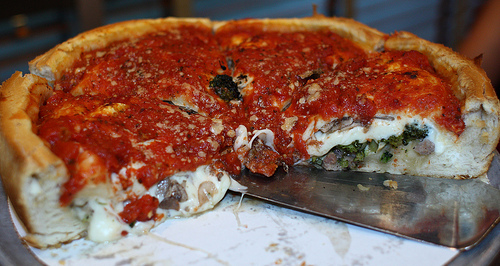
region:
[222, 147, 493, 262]
A silver spatula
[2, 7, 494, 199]
Half a pepperoni pizza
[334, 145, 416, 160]
Pieces of green broccoli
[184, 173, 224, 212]
A little mushroom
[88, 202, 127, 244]
Cheese coming from pizza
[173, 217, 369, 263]
A paper plate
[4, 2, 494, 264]
A half pizza on a paper plate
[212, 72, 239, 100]
A burnt piece of cheese on the pizza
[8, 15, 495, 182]
Pizza with sauce on top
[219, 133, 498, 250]
Spatula grabbing a slice of pizza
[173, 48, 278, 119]
a piece of spinach on pizza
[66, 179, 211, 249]
cheese and sauce on the pizza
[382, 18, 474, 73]
a piece of pizza crust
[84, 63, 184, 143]
sauce on the pizza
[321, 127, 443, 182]
spinach coming out of the pizza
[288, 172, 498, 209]
a piece of silver server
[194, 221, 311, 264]
a piece of cardboard under the pizza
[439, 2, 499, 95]
part of a workers arm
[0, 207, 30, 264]
part of the white table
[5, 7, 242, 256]
half of a spinach pizza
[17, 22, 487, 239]
The pizza has been partially eaten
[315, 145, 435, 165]
Spinach inside the pizza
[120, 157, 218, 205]
melted cheese inside pizza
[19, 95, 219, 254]
The pizza is thick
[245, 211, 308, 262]
Grease on the pizza board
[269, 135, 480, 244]
Pizza cutter on board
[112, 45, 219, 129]
Italian seasoning on the pizza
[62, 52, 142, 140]
The pizza does not have cheese on top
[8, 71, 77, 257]
The crust is brown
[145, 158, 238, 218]
Mushrooms inside the pizza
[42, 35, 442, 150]
The red sauce on the pizza.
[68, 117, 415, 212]
The white melted cheese inside of the pizza.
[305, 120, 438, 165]
The green food item inside of the pizza.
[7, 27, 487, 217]
The crust of the pizza.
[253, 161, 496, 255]
The silver spatula under the pizza.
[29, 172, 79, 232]
The dough inside of the crust on the left.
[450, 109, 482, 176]
The dough inside of the crust on the right.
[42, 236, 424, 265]
The grease stains on the white paper under the pizza.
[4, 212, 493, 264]
The edges of the silver platter the pizza is on.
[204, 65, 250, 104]
The green food item in the center of the pizza shaped in a circle.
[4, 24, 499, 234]
A deep dish pizza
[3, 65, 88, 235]
Thick crust on a pizza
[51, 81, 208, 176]
Red sauce on a pizza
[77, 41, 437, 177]
Toppings on a pizza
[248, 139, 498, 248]
A serving untensil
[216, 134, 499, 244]
A serving untensil under a pizza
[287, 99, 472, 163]
Chees on a pizza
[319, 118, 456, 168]
Broccoli on a pizza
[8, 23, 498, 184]
Tomato sauce on top of a pizza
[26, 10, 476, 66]
Crust on the edge of a pizza